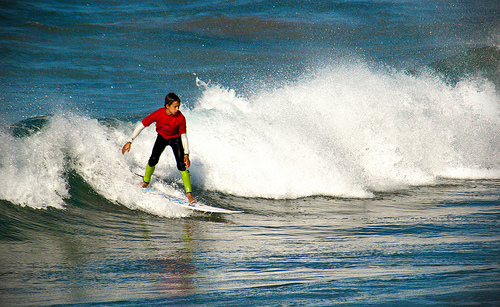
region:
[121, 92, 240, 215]
a male that is surfing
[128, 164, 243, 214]
a white surfboard with blue on it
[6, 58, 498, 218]
a wave with a white cap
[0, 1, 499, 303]
blue water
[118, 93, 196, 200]
boy with short black hair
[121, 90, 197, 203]
a boy wearing a wet suit and a t-shirt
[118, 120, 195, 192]
the wet suit is white, black, and yellow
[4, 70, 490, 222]
the wave is pushing the surfboard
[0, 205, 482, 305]
sunlight glistening on the water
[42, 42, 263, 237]
boy surfing in the ocean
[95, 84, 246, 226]
boy surfing in the ocean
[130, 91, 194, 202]
surfer in ocean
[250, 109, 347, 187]
waves in dark blue water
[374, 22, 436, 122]
waves in dark blue water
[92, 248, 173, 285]
waves in dark blue water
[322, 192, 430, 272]
waves in dark blue water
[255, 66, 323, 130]
waves in dark blue water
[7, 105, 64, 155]
waves in dark blue water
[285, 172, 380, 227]
waves in dark blue water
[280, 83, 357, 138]
waves in dark blue water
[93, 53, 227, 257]
the boy is surfing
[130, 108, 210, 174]
the shirt is red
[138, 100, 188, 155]
the shirt is red